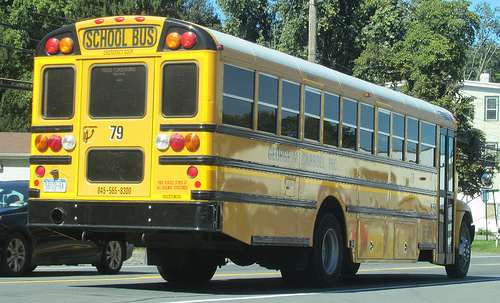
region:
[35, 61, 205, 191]
black tinted school bus windows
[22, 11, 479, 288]
School bus parked in parking lot.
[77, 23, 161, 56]
School bus written in black on back of bus.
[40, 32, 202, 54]
Flashing stop lights on back of bus.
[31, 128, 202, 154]
Brake and signal lights on back of bus.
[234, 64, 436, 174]
Windows along side of school bus.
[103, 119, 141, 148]
Bus number in black on back emergency door.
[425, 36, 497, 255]
Two story building across from school bus.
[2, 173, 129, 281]
Black car parked next to school bus.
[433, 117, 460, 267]
Passenger door on side of school bus.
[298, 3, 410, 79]
Top part of telephone pole with power lines.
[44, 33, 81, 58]
red and orange light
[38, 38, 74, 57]
red and orange signal light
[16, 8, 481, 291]
a yellow school bus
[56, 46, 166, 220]
an emergency exit on a school bus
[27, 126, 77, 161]
tail lights on a school bus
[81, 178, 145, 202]
a painted phone number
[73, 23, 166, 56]
a black and yellow school bus sign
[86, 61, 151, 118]
a dark tinted window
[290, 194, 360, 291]
school bus wheels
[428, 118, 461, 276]
tinted school bus door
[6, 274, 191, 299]
a road with yellow lines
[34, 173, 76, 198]
a blue and white license plate.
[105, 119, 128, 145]
the number seventy-nine in black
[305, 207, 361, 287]
a black tire on a silver rim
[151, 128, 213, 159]
the indicator lights for a bus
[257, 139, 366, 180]
the name of a school in black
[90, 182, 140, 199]
an emergency number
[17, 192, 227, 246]
the bumper of a bus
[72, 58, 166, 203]
the emergency exit door of a bus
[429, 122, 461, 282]
the main entrance to a bus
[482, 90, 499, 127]
the window of a house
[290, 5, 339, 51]
a telephone pole